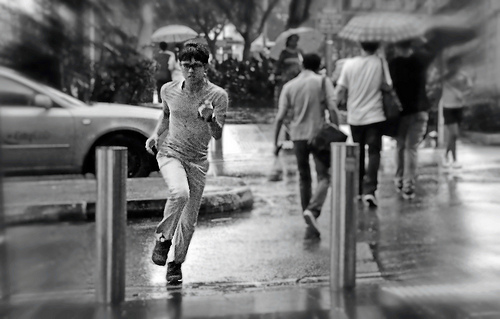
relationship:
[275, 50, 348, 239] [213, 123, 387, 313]
man walking in street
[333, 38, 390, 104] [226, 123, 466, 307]
man walking in street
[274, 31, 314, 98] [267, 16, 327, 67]
person standing under umbrella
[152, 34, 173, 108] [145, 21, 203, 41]
person standing under umbrella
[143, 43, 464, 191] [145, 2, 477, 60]
people carrying open umbrellas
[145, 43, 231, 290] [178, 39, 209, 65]
males wearing bangs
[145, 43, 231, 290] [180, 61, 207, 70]
males wearing glasses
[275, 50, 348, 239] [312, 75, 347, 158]
man carrying bag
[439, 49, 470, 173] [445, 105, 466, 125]
woman wearing shorts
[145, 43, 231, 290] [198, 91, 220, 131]
males has hand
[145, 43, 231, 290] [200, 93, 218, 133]
males has mobile telephone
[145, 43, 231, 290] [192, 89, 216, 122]
males has hand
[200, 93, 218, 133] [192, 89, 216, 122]
mobile telephone in hand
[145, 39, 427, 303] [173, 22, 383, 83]
males have hair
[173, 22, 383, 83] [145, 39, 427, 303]
hair on males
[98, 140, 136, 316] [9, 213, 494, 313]
post on sidewalk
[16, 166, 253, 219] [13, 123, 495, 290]
curb on road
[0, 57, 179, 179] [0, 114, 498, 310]
car on street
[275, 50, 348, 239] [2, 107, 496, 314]
man walking in road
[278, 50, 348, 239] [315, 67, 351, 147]
man has bag